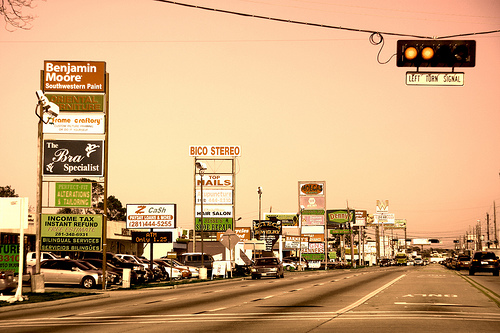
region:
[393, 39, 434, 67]
yellow lights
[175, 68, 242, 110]
the sky is clear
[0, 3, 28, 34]
braches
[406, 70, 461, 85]
a sign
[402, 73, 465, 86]
a black and white sign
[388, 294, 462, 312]
arrow in the street is white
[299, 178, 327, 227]
a billboard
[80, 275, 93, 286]
tire on the car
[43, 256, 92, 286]
a parked car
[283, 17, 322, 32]
a electrical line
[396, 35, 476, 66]
Traffic lights hanging from wire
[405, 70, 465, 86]
White sign under traffic light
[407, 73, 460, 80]
Black words on white sign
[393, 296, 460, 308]
White arrow on road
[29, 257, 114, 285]
Tan car parked near road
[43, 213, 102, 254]
Green and black sign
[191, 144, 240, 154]
White sign with red letters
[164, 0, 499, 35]
Wire holding traffic signal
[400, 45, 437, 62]
Two orange lights on signal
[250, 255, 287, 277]
Dark car driving on road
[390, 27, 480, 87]
traffic light on a pole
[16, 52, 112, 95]
sign on a pole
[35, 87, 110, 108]
sign on a pole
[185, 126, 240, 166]
sign on a pole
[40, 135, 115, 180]
sign on a pole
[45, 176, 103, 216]
sign on a pole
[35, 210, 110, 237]
sign on a pole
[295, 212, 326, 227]
sign on a pole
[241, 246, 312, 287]
car on a street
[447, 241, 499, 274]
car on a street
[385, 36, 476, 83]
signal light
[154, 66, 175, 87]
white clouds in blue sky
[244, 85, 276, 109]
white clouds in blue sky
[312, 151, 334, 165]
white clouds in blue sky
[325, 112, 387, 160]
white clouds in blue sky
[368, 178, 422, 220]
white clouds in blue sky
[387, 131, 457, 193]
white clouds in blue sky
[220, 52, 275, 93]
white clouds in blue sky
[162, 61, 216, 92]
white clouds in blue sky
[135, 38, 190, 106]
white clouds in blue sky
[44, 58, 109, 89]
this is a sign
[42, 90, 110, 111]
this is a sign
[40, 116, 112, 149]
this is a sign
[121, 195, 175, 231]
this is a sign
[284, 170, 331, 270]
this is a sign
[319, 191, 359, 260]
this is a sign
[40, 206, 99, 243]
this is a sign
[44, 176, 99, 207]
this is a sign